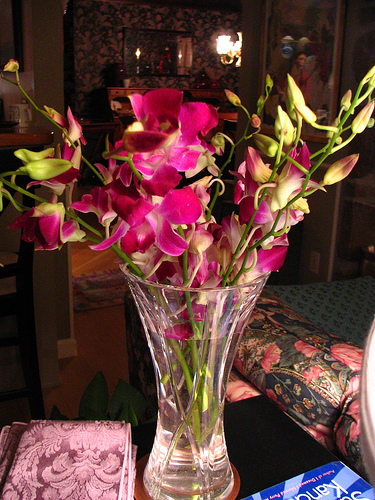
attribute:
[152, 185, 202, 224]
petal — bright, pink